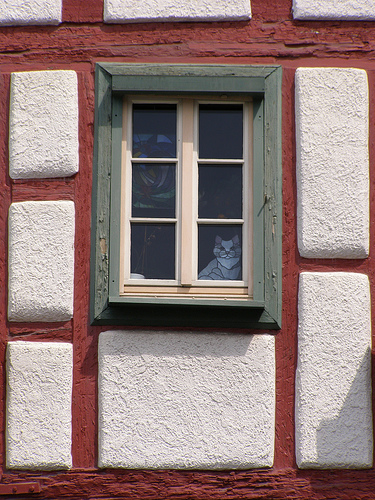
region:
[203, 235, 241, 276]
a panel shaped like a cat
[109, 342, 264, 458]
a white stucco square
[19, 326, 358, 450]
a red and white stucco wall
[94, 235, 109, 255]
missing paint on the window trim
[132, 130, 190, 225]
a colorful stained glass panel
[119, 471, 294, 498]
grooves in the wall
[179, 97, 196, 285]
white and tan window trim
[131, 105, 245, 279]
a paned glass window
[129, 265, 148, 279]
white flower pot in the window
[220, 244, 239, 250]
two eyes on the cat panel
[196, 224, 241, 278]
cat in the window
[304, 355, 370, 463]
shadow on the side of the buidling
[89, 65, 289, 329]
green wood around the window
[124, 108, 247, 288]
window with white lines on it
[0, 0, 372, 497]
white and brown wall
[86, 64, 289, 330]
window on the side of the building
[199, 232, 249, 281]
fake cat in the corner of the window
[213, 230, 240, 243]
two ears on top of the head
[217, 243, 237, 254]
two black eyes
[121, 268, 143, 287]
corner of the window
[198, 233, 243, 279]
grey and white cat on window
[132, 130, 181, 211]
colorful mosaic art in window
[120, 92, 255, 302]
tan frame of window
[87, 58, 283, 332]
green wooden outer frame of window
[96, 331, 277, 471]
large white block of building under window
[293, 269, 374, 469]
long white block of building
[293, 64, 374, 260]
long white block near window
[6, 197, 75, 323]
white block to left of window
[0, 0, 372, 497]
red wood trim of building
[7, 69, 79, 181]
small white block near window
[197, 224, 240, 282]
Stained glass cat pattern in window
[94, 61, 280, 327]
Stained glass window with six panes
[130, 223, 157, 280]
Potted plant inside the building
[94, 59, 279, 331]
Green wooden window frame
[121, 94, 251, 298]
White window panes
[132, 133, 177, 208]
Multicolored stained glass design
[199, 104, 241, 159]
Plain glass window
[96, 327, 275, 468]
White patch of stucco beneath the window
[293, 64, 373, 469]
Two white patches of stucco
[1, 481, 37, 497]
Metal with two bolts painted red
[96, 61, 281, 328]
the outside fram of the window is green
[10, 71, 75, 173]
white cement bricks are placed in varying sizes on the outside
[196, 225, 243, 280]
a cat pillow is in the window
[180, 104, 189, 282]
the panel in the center of the window is beige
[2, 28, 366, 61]
the wood beam is painted red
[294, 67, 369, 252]
this is a rectangle shaped brick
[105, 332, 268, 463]
a large square brick is under the window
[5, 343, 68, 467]
a small rectange is on the side of the wall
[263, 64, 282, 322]
the paint is chipping at various spots on the frame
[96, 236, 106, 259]
no paint is on this piece of wood